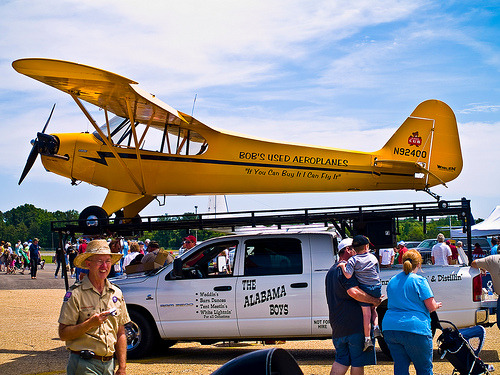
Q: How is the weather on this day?
A: It is cloudy.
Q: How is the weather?
A: It is cloudy.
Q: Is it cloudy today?
A: Yes, it is cloudy.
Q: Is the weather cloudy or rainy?
A: It is cloudy.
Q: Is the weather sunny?
A: No, it is cloudy.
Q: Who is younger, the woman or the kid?
A: The kid is younger than the woman.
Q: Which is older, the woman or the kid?
A: The woman is older than the kid.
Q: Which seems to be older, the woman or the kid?
A: The woman is older than the kid.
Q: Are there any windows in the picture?
A: Yes, there is a window.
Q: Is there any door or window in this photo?
A: Yes, there is a window.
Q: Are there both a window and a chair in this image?
A: No, there is a window but no chairs.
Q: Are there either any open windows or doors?
A: Yes, there is an open window.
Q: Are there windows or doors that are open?
A: Yes, the window is open.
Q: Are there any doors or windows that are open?
A: Yes, the window is open.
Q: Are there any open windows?
A: Yes, there is an open window.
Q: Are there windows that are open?
A: Yes, there is a window that is open.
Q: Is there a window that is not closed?
A: Yes, there is a open window.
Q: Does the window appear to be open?
A: Yes, the window is open.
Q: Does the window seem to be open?
A: Yes, the window is open.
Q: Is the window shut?
A: No, the window is open.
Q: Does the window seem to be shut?
A: No, the window is open.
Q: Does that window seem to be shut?
A: No, the window is open.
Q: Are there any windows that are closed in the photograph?
A: No, there is a window but it is open.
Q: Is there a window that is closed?
A: No, there is a window but it is open.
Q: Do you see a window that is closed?
A: No, there is a window but it is open.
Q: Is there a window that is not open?
A: No, there is a window but it is open.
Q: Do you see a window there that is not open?
A: No, there is a window but it is open.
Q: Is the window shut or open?
A: The window is open.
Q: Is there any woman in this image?
A: Yes, there is a woman.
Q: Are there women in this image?
A: Yes, there is a woman.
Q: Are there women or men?
A: Yes, there is a woman.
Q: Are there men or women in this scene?
A: Yes, there is a woman.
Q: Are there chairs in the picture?
A: No, there are no chairs.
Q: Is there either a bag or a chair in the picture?
A: No, there are no chairs or bags.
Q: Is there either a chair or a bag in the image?
A: No, there are no chairs or bags.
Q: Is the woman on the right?
A: Yes, the woman is on the right of the image.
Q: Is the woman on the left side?
A: No, the woman is on the right of the image.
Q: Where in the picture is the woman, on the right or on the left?
A: The woman is on the right of the image.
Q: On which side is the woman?
A: The woman is on the right of the image.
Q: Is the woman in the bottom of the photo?
A: Yes, the woman is in the bottom of the image.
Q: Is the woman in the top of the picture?
A: No, the woman is in the bottom of the image.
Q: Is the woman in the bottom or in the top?
A: The woman is in the bottom of the image.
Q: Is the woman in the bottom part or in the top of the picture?
A: The woman is in the bottom of the image.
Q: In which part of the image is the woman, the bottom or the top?
A: The woman is in the bottom of the image.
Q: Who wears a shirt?
A: The woman wears a shirt.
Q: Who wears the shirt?
A: The woman wears a shirt.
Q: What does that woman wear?
A: The woman wears a shirt.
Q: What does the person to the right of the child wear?
A: The woman wears a shirt.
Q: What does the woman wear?
A: The woman wears a shirt.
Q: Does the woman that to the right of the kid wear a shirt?
A: Yes, the woman wears a shirt.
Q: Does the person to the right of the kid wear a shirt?
A: Yes, the woman wears a shirt.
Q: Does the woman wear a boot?
A: No, the woman wears a shirt.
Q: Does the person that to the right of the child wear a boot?
A: No, the woman wears a shirt.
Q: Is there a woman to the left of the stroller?
A: Yes, there is a woman to the left of the stroller.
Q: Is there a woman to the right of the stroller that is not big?
A: No, the woman is to the left of the stroller.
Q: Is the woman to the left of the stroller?
A: Yes, the woman is to the left of the stroller.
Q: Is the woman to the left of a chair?
A: No, the woman is to the left of the stroller.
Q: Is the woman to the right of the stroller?
A: No, the woman is to the left of the stroller.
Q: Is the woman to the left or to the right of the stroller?
A: The woman is to the left of the stroller.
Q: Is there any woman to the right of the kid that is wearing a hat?
A: Yes, there is a woman to the right of the child.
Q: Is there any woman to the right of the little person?
A: Yes, there is a woman to the right of the child.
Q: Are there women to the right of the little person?
A: Yes, there is a woman to the right of the child.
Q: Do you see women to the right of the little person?
A: Yes, there is a woman to the right of the child.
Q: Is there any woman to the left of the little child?
A: No, the woman is to the right of the kid.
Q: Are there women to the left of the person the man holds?
A: No, the woman is to the right of the kid.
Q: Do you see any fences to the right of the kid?
A: No, there is a woman to the right of the kid.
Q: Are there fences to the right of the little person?
A: No, there is a woman to the right of the kid.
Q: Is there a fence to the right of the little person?
A: No, there is a woman to the right of the kid.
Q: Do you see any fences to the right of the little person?
A: No, there is a woman to the right of the kid.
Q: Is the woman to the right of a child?
A: Yes, the woman is to the right of a child.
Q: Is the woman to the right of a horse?
A: No, the woman is to the right of a child.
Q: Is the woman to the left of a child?
A: No, the woman is to the right of a child.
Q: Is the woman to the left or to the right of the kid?
A: The woman is to the right of the kid.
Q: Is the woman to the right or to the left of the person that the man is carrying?
A: The woman is to the right of the kid.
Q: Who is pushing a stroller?
A: The woman is pushing a stroller.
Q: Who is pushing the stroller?
A: The woman is pushing a stroller.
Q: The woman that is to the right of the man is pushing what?
A: The woman is pushing a stroller.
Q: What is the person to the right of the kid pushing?
A: The woman is pushing a stroller.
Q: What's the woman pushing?
A: The woman is pushing a stroller.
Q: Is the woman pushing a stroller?
A: Yes, the woman is pushing a stroller.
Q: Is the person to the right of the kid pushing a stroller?
A: Yes, the woman is pushing a stroller.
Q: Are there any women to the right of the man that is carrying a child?
A: Yes, there is a woman to the right of the man.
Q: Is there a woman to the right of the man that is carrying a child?
A: Yes, there is a woman to the right of the man.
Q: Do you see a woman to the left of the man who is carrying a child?
A: No, the woman is to the right of the man.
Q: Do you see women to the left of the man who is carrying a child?
A: No, the woman is to the right of the man.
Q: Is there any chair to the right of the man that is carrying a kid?
A: No, there is a woman to the right of the man.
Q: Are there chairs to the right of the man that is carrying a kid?
A: No, there is a woman to the right of the man.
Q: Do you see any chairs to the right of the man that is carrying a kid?
A: No, there is a woman to the right of the man.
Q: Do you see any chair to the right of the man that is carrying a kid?
A: No, there is a woman to the right of the man.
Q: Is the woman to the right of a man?
A: Yes, the woman is to the right of a man.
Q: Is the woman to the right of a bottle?
A: No, the woman is to the right of a man.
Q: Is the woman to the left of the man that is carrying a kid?
A: No, the woman is to the right of the man.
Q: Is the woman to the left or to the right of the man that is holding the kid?
A: The woman is to the right of the man.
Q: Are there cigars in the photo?
A: No, there are no cigars.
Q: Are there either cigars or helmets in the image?
A: No, there are no cigars or helmets.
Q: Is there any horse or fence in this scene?
A: No, there are no fences or horses.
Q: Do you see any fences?
A: No, there are no fences.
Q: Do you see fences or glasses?
A: No, there are no fences or glasses.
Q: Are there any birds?
A: No, there are no birds.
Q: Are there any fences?
A: No, there are no fences.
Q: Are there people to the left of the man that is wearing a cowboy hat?
A: Yes, there is a person to the left of the man.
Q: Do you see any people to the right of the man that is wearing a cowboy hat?
A: No, the person is to the left of the man.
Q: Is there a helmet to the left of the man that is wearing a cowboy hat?
A: No, there is a person to the left of the man.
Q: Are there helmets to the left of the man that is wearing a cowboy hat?
A: No, there is a person to the left of the man.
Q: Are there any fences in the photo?
A: No, there are no fences.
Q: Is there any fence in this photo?
A: No, there are no fences.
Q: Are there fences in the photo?
A: No, there are no fences.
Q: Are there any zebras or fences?
A: No, there are no fences or zebras.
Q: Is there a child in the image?
A: Yes, there is a child.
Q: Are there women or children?
A: Yes, there is a child.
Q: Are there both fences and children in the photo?
A: No, there is a child but no fences.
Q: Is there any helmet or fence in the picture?
A: No, there are no fences or helmets.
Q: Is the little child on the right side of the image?
A: Yes, the kid is on the right of the image.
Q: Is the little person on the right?
A: Yes, the kid is on the right of the image.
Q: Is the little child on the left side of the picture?
A: No, the kid is on the right of the image.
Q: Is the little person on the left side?
A: No, the kid is on the right of the image.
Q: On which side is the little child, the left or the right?
A: The kid is on the right of the image.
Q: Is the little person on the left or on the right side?
A: The kid is on the right of the image.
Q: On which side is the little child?
A: The kid is on the right of the image.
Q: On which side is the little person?
A: The kid is on the right of the image.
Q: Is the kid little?
A: Yes, the kid is little.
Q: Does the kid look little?
A: Yes, the kid is little.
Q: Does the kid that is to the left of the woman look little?
A: Yes, the kid is little.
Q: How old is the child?
A: The child is little.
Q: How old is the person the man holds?
A: The child is little.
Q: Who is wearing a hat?
A: The kid is wearing a hat.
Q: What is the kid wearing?
A: The kid is wearing a hat.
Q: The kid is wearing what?
A: The kid is wearing a hat.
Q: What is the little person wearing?
A: The kid is wearing a hat.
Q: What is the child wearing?
A: The kid is wearing a hat.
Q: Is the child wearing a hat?
A: Yes, the child is wearing a hat.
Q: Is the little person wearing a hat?
A: Yes, the child is wearing a hat.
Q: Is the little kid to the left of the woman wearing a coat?
A: No, the child is wearing a hat.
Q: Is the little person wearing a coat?
A: No, the child is wearing a hat.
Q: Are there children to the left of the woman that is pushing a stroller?
A: Yes, there is a child to the left of the woman.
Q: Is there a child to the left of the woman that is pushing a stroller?
A: Yes, there is a child to the left of the woman.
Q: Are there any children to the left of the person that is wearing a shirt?
A: Yes, there is a child to the left of the woman.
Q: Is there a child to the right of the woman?
A: No, the child is to the left of the woman.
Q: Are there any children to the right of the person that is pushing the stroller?
A: No, the child is to the left of the woman.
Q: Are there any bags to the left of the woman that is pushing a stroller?
A: No, there is a child to the left of the woman.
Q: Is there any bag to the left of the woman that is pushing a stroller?
A: No, there is a child to the left of the woman.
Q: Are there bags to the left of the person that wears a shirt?
A: No, there is a child to the left of the woman.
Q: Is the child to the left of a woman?
A: Yes, the child is to the left of a woman.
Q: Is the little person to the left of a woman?
A: Yes, the child is to the left of a woman.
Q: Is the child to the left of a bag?
A: No, the child is to the left of a woman.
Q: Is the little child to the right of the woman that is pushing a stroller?
A: No, the kid is to the left of the woman.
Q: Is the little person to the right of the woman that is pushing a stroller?
A: No, the kid is to the left of the woman.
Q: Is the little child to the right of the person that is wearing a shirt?
A: No, the kid is to the left of the woman.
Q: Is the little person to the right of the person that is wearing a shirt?
A: No, the kid is to the left of the woman.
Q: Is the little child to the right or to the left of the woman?
A: The kid is to the left of the woman.